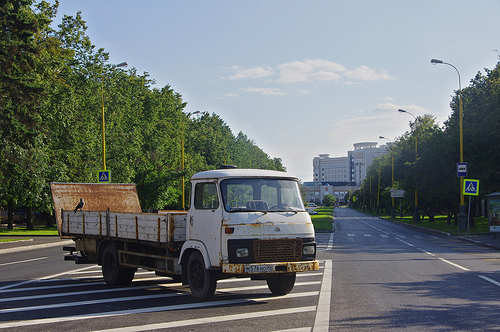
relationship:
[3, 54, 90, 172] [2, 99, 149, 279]
tall trees to left